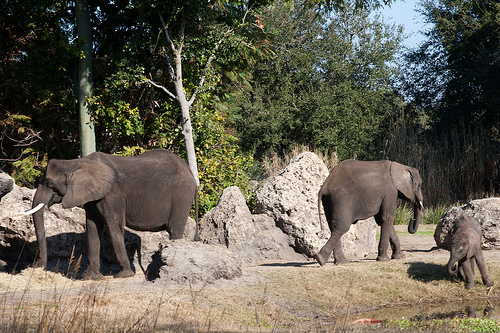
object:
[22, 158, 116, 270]
head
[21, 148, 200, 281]
elephant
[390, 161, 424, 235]
head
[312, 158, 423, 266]
elephant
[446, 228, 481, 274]
head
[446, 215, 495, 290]
elephant